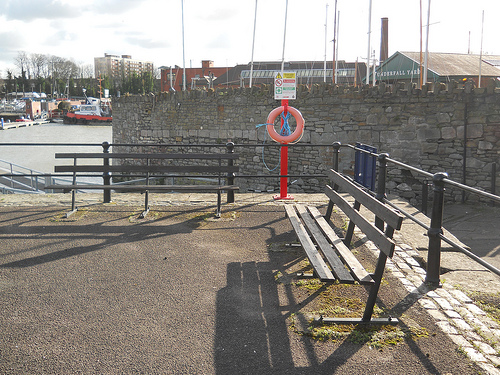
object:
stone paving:
[0, 192, 498, 373]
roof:
[400, 53, 500, 77]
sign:
[273, 71, 298, 99]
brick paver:
[418, 299, 434, 310]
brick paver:
[451, 317, 468, 330]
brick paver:
[466, 301, 485, 315]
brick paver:
[410, 274, 422, 283]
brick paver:
[396, 260, 410, 270]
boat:
[59, 105, 109, 126]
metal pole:
[0, 142, 348, 148]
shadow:
[214, 260, 334, 373]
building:
[110, 52, 500, 205]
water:
[0, 122, 112, 182]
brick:
[333, 127, 347, 131]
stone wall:
[111, 80, 499, 208]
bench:
[282, 167, 404, 323]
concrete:
[126, 303, 201, 332]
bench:
[44, 152, 240, 219]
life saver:
[264, 102, 305, 142]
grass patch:
[291, 252, 409, 350]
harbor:
[0, 90, 83, 133]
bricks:
[478, 362, 500, 374]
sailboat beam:
[365, 0, 371, 83]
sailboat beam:
[281, 0, 290, 72]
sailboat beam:
[248, 0, 260, 88]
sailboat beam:
[180, 0, 186, 91]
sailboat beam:
[422, 0, 431, 83]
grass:
[290, 222, 431, 348]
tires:
[62, 116, 72, 123]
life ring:
[266, 105, 306, 143]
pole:
[281, 99, 288, 199]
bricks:
[448, 334, 475, 348]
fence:
[0, 140, 350, 202]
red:
[282, 168, 285, 174]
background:
[0, 0, 500, 374]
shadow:
[1, 206, 217, 272]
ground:
[0, 188, 499, 374]